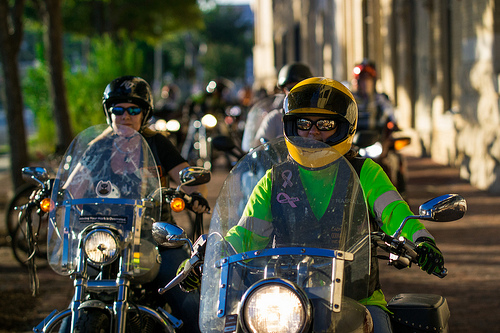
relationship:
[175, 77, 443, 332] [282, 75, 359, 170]
man wearing helmet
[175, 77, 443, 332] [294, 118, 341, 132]
man wearing sunglasses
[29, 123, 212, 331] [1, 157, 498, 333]
motorcycle drives down road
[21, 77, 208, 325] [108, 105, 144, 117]
woman with sunglasses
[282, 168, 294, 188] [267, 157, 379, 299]
ribbon on vest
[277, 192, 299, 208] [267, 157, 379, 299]
ribbon on vest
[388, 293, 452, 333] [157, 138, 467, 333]
saddlebag for motorcycle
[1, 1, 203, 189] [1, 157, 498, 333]
trees line road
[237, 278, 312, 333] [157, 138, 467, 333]
headlight on motorcycle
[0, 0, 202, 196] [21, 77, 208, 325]
tree behind woman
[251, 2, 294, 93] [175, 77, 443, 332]
building behind man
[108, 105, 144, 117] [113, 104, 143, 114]
sunglasses with lenses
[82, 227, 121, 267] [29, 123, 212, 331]
light on motorcycle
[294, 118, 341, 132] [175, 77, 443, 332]
sunglasses on man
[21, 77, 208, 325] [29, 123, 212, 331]
woman riding motorcycle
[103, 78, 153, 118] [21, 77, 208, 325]
helmet on woman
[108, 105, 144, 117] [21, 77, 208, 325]
sunglasses on woman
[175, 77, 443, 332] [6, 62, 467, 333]
man in rally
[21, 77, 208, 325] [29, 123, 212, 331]
woman on motorcycle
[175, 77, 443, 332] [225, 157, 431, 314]
man wearing shirt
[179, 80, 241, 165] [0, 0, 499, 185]
person in background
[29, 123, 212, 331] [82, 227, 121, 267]
motorcycle with light